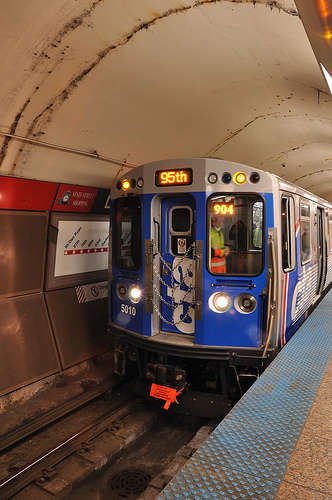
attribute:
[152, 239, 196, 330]
chains — hanging, metal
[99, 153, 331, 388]
train — blue and silver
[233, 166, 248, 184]
light — bright, shinning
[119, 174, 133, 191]
light — bright, shinning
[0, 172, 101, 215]
sign — red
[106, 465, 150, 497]
lid — metallic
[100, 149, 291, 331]
train — underground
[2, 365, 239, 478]
track — train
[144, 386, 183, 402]
sign — orange , bright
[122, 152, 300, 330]
train — red, white, blue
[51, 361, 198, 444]
track — railway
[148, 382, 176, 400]
sign — red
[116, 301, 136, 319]
number — 5010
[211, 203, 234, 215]
sign — illuminated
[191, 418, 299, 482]
circles — blue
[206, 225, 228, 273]
safety clothing — orange, green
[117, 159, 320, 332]
train — orange and yellow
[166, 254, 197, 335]
letters — white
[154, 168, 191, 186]
light — orange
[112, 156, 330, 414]
train — white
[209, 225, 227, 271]
vest — yellow and orange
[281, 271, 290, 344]
stripe — white, red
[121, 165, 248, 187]
light — yellow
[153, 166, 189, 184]
number — bordered, 95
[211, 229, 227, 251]
vest — green